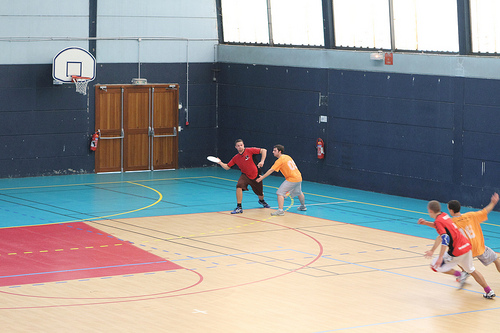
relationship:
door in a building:
[72, 68, 199, 199] [36, 8, 486, 323]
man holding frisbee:
[204, 137, 268, 211] [205, 155, 219, 162]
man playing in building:
[215, 138, 271, 214] [2, 0, 495, 330]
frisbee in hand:
[203, 152, 224, 166] [215, 157, 222, 167]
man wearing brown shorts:
[215, 138, 271, 214] [237, 169, 261, 197]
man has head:
[215, 138, 271, 214] [232, 137, 246, 152]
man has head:
[215, 138, 271, 214] [271, 144, 285, 158]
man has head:
[215, 138, 271, 214] [446, 197, 462, 213]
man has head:
[215, 138, 271, 214] [426, 198, 441, 215]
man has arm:
[215, 138, 271, 214] [206, 147, 231, 189]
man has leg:
[215, 138, 271, 214] [250, 176, 271, 207]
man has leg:
[215, 138, 271, 214] [271, 190, 283, 214]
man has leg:
[215, 138, 271, 214] [296, 190, 307, 212]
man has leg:
[215, 138, 271, 214] [229, 185, 243, 213]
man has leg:
[215, 138, 271, 214] [253, 185, 271, 209]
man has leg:
[215, 138, 271, 214] [469, 269, 498, 299]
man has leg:
[215, 138, 271, 214] [437, 264, 469, 287]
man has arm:
[215, 138, 271, 214] [426, 215, 451, 279]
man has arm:
[215, 138, 271, 214] [434, 221, 450, 258]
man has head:
[215, 138, 271, 214] [420, 201, 441, 216]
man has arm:
[215, 138, 271, 214] [431, 220, 448, 273]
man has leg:
[215, 138, 271, 214] [449, 250, 498, 300]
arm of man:
[434, 221, 450, 258] [215, 138, 271, 214]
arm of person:
[434, 219, 450, 268] [427, 197, 497, 298]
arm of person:
[434, 221, 450, 258] [424, 191, 499, 288]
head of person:
[441, 197, 476, 222] [424, 175, 498, 293]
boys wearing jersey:
[215, 136, 312, 218] [227, 153, 306, 183]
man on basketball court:
[215, 138, 271, 214] [0, 166, 500, 333]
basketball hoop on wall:
[69, 71, 94, 98] [0, 0, 225, 180]